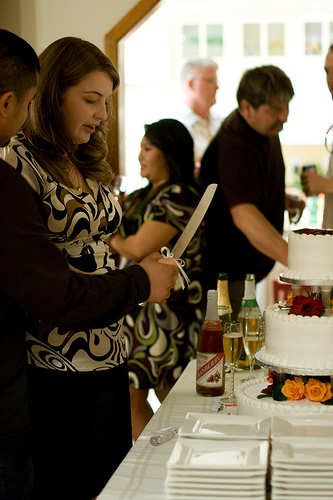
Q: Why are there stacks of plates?
A: For cake.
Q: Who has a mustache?
A: The man.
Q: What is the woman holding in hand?
A: Knife.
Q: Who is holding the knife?
A: Couple.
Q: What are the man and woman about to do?
A: Cut the cake.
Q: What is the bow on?
A: Knife.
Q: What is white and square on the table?
A: Plates.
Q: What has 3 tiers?
A: Cake.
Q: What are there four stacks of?
A: Plates.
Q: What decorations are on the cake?
A: Flowers.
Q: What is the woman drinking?
A: Drinking champagne.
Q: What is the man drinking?
A: Champagne.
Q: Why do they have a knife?
A: To cut the cake.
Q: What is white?
A: Cake.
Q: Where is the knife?
A: In their hands.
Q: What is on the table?
A: Plates.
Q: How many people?
A: 6.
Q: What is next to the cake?
A: Bottles.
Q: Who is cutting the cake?
A: The woman.